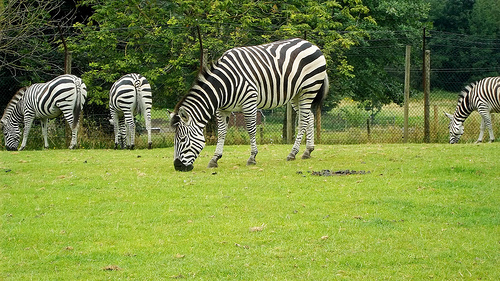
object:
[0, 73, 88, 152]
zebra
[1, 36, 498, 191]
zebras field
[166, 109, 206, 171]
head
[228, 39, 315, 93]
stripes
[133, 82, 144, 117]
tail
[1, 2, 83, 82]
tree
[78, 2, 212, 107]
tree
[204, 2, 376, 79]
tree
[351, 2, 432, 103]
tree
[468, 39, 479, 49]
leaf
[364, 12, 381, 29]
leaf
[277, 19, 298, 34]
leaf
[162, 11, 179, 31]
leaf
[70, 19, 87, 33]
leaf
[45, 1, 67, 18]
branch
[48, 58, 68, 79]
branch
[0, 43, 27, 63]
branch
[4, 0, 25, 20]
branch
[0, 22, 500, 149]
fence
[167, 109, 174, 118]
ears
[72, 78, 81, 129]
tail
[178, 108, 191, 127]
ear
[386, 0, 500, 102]
tree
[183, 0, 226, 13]
leaves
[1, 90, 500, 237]
zebra field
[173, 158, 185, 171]
nose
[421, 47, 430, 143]
pole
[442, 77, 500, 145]
zebra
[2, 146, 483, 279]
grass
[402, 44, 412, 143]
pole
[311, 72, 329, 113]
tail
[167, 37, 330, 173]
zebra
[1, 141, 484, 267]
field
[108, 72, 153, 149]
zebra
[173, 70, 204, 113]
manes